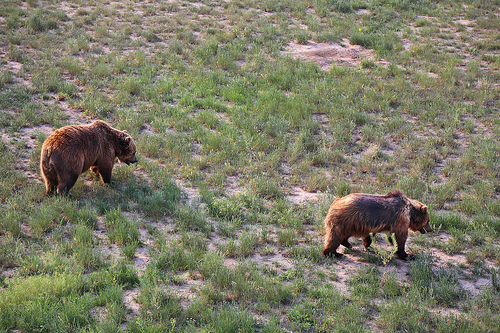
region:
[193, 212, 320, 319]
the grassesa re green in color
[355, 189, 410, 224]
the wolf has a blck back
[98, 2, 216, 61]
the land has patches aopg sand and grasses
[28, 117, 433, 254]
both the wolves are in the field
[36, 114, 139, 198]
a bear standing in grass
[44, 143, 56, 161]
a bear's tail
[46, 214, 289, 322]
grass and weeds in a field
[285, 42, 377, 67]
an open spot of dirt in field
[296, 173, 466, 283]
bear with sunlight on its fur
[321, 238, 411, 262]
bear's large paws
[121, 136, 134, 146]
ear of a bear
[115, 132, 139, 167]
head of a bear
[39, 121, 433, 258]
The bears are brown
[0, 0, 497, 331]
The bears are in an open field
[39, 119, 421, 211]
The sun is shining on there backs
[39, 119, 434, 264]
The bears are facing in the same directions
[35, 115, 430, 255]
The bears have lots of fur.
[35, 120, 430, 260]
The bears have three paws on the ground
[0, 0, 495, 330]
The bears are walking in daylight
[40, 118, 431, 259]
There are only 2 bears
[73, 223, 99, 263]
green grass on ground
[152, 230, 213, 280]
green grass on ground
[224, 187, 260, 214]
green grass on ground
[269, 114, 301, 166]
green grass on ground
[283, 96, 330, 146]
green grass on ground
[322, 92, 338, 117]
green grass on ground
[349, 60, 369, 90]
green grass on ground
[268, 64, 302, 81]
green grass on ground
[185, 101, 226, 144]
green grass on ground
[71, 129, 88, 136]
brown fur on bear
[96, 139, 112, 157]
brown fur on bear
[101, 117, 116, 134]
brown fur on bear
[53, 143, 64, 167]
brown fur on bear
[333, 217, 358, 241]
brown fur on bear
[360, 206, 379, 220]
brown fur on bear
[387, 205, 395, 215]
brown fur on bear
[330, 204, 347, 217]
brown fur on bear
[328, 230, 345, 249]
brown fur on bear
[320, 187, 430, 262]
bear is in the field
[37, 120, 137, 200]
bear is in the field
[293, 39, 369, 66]
mound of dirt is in the grass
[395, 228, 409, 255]
leg belongs to bear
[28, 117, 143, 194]
large brown grizzley bear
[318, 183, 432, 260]
large brown grizzley bear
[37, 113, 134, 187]
large brown grizzley bear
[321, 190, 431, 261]
large brown grizzley bear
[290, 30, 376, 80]
patch of brown dirt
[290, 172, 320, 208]
patch of brown dirt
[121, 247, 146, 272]
patch of brown dirt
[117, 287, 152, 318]
patch of brown dirt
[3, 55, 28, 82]
patch of brown dirt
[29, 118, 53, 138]
patch of brown dirt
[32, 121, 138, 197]
The brown bear on the left.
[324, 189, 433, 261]
The brown bear on the left.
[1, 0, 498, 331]
Two bears in a grassland.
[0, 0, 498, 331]
A grassland in the wild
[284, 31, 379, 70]
An open dirt patch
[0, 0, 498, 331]
The lesser growing grass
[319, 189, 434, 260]
The malnourished brown bear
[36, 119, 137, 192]
The healthy brown bear